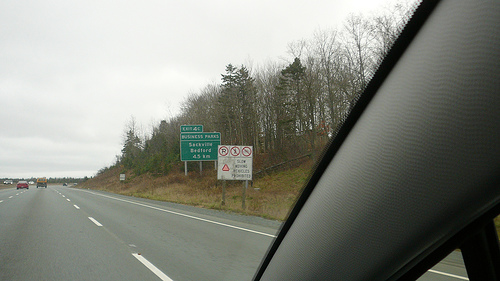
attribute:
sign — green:
[179, 129, 222, 166]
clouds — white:
[0, 0, 422, 177]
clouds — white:
[0, 6, 355, 161]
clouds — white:
[1, 7, 186, 99]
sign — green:
[2, 184, 287, 279]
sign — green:
[174, 111, 252, 202]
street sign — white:
[215, 145, 255, 179]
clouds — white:
[14, 8, 308, 169]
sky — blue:
[0, 0, 420, 177]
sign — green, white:
[178, 120, 223, 162]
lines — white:
[1, 187, 171, 277]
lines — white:
[83, 195, 243, 281]